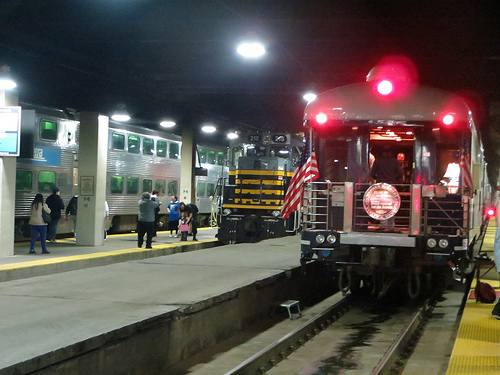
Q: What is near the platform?
A: A train track.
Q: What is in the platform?
A: A train.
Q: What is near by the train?
A: Another train.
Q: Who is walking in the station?
A: Passengers.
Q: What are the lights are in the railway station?
A: Red.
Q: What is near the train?
A: The railway platform.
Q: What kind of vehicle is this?
A: Train.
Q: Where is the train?
A: Train tracks.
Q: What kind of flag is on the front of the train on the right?
A: American flag.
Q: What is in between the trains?
A: Paved platform.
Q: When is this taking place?
A: Night time.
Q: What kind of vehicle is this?
A: Train.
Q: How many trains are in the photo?
A: Two.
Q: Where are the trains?
A: Train station.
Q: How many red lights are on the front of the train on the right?
A: Three.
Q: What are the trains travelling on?
A: Train tracks.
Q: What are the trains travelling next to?
A: Platform.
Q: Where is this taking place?
A: At a train station.